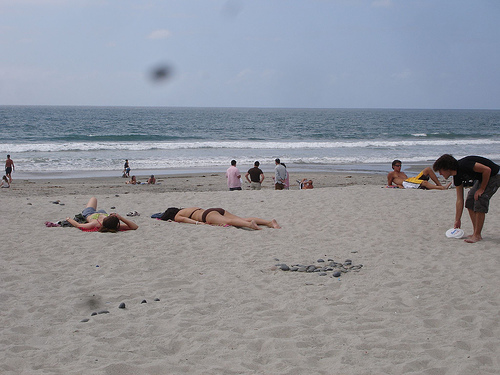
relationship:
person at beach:
[247, 159, 266, 192] [4, 0, 499, 374]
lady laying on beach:
[155, 204, 282, 233] [4, 243, 499, 374]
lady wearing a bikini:
[155, 204, 282, 233] [187, 206, 229, 226]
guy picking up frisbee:
[434, 151, 500, 245] [444, 226, 467, 241]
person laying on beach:
[63, 193, 140, 236] [4, 243, 499, 374]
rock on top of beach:
[332, 269, 344, 281] [4, 243, 499, 374]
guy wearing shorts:
[385, 159, 453, 192] [407, 168, 429, 188]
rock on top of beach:
[332, 269, 344, 281] [4, 0, 499, 374]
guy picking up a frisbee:
[434, 151, 500, 245] [444, 226, 467, 241]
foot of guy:
[467, 235, 484, 246] [434, 151, 500, 245]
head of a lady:
[165, 206, 180, 222] [155, 204, 282, 233]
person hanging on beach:
[247, 159, 266, 192] [4, 0, 499, 374]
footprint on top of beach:
[422, 315, 441, 332] [4, 243, 499, 374]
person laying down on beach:
[63, 193, 140, 236] [4, 243, 499, 374]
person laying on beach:
[63, 193, 140, 236] [4, 0, 499, 374]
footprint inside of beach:
[480, 326, 500, 340] [4, 243, 499, 374]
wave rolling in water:
[4, 155, 500, 171] [0, 107, 499, 179]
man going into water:
[5, 153, 17, 184] [0, 107, 499, 179]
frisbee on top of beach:
[444, 226, 467, 241] [4, 243, 499, 374]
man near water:
[5, 153, 17, 184] [0, 107, 499, 179]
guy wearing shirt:
[434, 151, 500, 245] [452, 154, 499, 187]